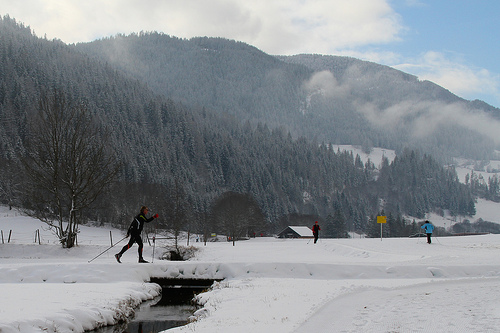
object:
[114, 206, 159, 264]
person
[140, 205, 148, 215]
head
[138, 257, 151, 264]
shoe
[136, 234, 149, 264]
leg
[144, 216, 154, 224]
arm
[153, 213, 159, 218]
glove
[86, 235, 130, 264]
pole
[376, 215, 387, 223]
sign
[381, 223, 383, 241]
post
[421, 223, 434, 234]
coat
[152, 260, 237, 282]
bridge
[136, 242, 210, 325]
river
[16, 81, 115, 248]
tree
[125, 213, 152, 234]
jacket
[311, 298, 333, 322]
line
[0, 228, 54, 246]
fence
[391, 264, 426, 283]
snow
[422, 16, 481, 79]
sky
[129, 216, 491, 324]
field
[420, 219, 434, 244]
people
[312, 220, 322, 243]
man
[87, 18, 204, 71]
mountain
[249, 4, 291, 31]
cloud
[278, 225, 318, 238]
cottage